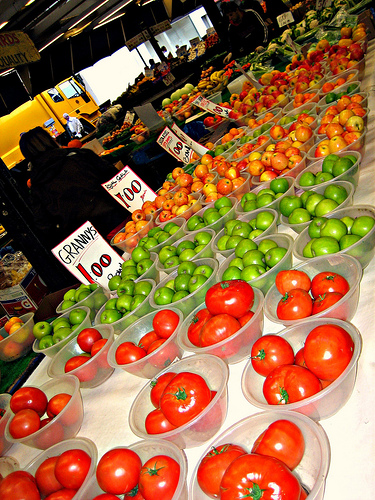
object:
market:
[1, 1, 374, 498]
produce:
[325, 92, 335, 104]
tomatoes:
[277, 287, 312, 320]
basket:
[240, 315, 361, 416]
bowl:
[279, 181, 352, 235]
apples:
[314, 198, 337, 216]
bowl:
[306, 135, 366, 166]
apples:
[328, 136, 349, 154]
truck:
[0, 153, 102, 247]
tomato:
[160, 372, 212, 426]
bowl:
[292, 206, 374, 271]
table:
[0, 40, 375, 500]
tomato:
[303, 324, 355, 382]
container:
[4, 372, 84, 450]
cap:
[61, 113, 67, 119]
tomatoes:
[76, 327, 100, 353]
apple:
[280, 195, 303, 217]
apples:
[175, 272, 190, 292]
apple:
[153, 286, 174, 306]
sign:
[156, 125, 199, 167]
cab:
[41, 77, 101, 131]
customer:
[18, 127, 128, 256]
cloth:
[0, 40, 375, 499]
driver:
[62, 112, 86, 140]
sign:
[0, 30, 40, 69]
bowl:
[149, 257, 221, 320]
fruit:
[9, 386, 48, 417]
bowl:
[32, 305, 93, 358]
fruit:
[31, 322, 51, 338]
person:
[219, 1, 267, 64]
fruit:
[215, 453, 296, 500]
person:
[97, 107, 115, 136]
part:
[246, 483, 262, 498]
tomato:
[218, 452, 300, 499]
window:
[57, 80, 84, 100]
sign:
[51, 218, 125, 294]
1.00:
[76, 253, 114, 284]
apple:
[193, 164, 208, 180]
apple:
[247, 151, 264, 163]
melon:
[161, 96, 170, 106]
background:
[0, 0, 375, 499]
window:
[143, 16, 202, 62]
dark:
[36, 171, 52, 224]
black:
[54, 185, 80, 225]